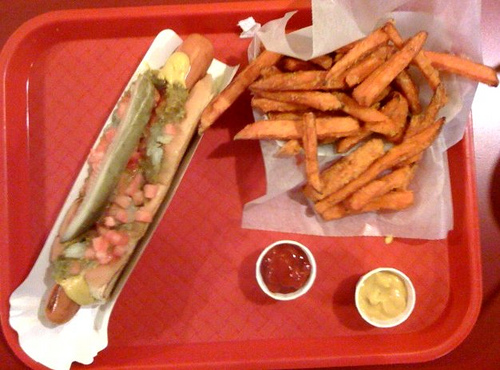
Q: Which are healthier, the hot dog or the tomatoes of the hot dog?
A: The tomatoes are healthier than the hot dog.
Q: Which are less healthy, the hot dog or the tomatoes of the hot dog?
A: The hot dog are less healthy than the tomatoes.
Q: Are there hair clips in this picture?
A: No, there are no hair clips.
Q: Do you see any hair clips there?
A: No, there are no hair clips.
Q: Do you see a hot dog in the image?
A: Yes, there is a hot dog.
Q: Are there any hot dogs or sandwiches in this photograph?
A: Yes, there is a hot dog.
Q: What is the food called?
A: The food is a hot dog.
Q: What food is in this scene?
A: The food is a hot dog.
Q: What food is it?
A: The food is a hot dog.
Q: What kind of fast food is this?
A: This is a hot dog.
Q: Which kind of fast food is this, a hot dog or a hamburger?
A: This is a hot dog.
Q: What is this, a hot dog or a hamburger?
A: This is a hot dog.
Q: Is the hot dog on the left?
A: Yes, the hot dog is on the left of the image.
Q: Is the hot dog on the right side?
A: No, the hot dog is on the left of the image.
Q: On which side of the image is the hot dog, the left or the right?
A: The hot dog is on the left of the image.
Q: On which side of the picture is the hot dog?
A: The hot dog is on the left of the image.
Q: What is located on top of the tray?
A: The hot dog is on top of the tray.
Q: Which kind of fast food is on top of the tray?
A: The food is a hot dog.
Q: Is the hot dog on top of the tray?
A: Yes, the hot dog is on top of the tray.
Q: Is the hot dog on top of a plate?
A: No, the hot dog is on top of the tray.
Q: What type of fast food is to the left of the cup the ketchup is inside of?
A: The food is a hot dog.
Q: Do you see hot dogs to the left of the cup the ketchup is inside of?
A: Yes, there is a hot dog to the left of the cup.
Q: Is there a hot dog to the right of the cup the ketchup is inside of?
A: No, the hot dog is to the left of the cup.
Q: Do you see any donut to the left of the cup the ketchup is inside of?
A: No, there is a hot dog to the left of the cup.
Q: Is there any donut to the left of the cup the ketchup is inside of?
A: No, there is a hot dog to the left of the cup.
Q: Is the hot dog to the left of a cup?
A: Yes, the hot dog is to the left of a cup.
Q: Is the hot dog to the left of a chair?
A: No, the hot dog is to the left of a cup.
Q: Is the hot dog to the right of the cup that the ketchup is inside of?
A: No, the hot dog is to the left of the cup.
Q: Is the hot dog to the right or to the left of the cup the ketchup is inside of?
A: The hot dog is to the left of the cup.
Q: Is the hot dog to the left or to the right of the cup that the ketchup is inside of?
A: The hot dog is to the left of the cup.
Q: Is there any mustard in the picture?
A: Yes, there is mustard.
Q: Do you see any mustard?
A: Yes, there is mustard.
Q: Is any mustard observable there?
A: Yes, there is mustard.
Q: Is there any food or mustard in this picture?
A: Yes, there is mustard.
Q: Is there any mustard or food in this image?
A: Yes, there is mustard.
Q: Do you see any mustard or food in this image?
A: Yes, there is mustard.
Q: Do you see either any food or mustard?
A: Yes, there is mustard.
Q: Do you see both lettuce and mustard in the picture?
A: No, there is mustard but no lettuce.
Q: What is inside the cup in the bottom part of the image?
A: The mustard is inside the cup.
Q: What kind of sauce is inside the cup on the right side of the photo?
A: The sauce is mustard.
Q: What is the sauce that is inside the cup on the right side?
A: The sauce is mustard.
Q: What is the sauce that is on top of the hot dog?
A: The sauce is mustard.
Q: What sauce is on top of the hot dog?
A: The sauce is mustard.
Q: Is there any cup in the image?
A: Yes, there is a cup.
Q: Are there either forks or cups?
A: Yes, there is a cup.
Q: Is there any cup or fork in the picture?
A: Yes, there is a cup.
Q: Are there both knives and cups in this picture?
A: No, there is a cup but no knives.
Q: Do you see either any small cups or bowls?
A: Yes, there is a small cup.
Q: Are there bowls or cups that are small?
A: Yes, the cup is small.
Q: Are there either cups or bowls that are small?
A: Yes, the cup is small.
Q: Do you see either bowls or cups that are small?
A: Yes, the cup is small.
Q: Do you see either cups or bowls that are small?
A: Yes, the cup is small.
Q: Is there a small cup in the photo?
A: Yes, there is a small cup.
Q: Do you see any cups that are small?
A: Yes, there is a cup that is small.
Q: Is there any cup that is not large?
A: Yes, there is a small cup.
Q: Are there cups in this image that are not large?
A: Yes, there is a small cup.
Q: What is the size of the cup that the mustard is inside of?
A: The cup is small.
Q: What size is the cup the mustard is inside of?
A: The cup is small.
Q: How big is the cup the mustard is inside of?
A: The cup is small.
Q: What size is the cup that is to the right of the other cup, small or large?
A: The cup is small.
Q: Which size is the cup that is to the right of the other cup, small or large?
A: The cup is small.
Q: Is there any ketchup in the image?
A: Yes, there is ketchup.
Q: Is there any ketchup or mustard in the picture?
A: Yes, there is ketchup.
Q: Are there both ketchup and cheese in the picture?
A: No, there is ketchup but no cheese.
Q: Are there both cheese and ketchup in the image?
A: No, there is ketchup but no cheese.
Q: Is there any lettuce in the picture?
A: No, there is no lettuce.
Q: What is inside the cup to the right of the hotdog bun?
A: The ketchup is inside the cup.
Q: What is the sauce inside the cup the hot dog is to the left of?
A: The sauce is ketchup.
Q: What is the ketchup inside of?
A: The ketchup is inside the cup.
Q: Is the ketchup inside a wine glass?
A: No, the ketchup is inside a cup.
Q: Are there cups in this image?
A: Yes, there is a cup.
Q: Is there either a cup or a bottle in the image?
A: Yes, there is a cup.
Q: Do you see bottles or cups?
A: Yes, there is a cup.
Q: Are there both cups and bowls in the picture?
A: No, there is a cup but no bowls.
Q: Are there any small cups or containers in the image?
A: Yes, there is a small cup.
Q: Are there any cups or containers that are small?
A: Yes, the cup is small.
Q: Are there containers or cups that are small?
A: Yes, the cup is small.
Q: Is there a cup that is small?
A: Yes, there is a cup that is small.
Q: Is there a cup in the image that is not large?
A: Yes, there is a small cup.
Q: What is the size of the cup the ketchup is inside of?
A: The cup is small.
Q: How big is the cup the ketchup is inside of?
A: The cup is small.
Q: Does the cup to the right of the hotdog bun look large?
A: No, the cup is small.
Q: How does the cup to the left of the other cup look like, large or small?
A: The cup is small.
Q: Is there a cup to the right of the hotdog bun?
A: Yes, there is a cup to the right of the hotdog bun.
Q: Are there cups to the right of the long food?
A: Yes, there is a cup to the right of the hotdog bun.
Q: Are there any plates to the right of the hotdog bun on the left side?
A: No, there is a cup to the right of the hotdog bun.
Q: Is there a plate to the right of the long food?
A: No, there is a cup to the right of the hotdog bun.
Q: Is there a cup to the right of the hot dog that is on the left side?
A: Yes, there is a cup to the right of the hot dog.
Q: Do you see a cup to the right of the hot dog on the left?
A: Yes, there is a cup to the right of the hot dog.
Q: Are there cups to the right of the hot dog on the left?
A: Yes, there is a cup to the right of the hot dog.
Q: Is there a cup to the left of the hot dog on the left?
A: No, the cup is to the right of the hot dog.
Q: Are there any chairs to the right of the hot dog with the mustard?
A: No, there is a cup to the right of the hot dog.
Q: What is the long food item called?
A: The food item is a hotdog bun.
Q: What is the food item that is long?
A: The food item is a hotdog bun.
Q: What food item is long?
A: The food item is a hotdog bun.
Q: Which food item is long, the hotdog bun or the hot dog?
A: The hotdog bun is long.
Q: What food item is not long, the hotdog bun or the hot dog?
A: The hot dog is not long.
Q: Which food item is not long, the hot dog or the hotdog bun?
A: The hot dog is not long.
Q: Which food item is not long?
A: The food item is a hot dog.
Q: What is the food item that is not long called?
A: The food item is a hot dog.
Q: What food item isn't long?
A: The food item is a hot dog.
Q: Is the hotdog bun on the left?
A: Yes, the hotdog bun is on the left of the image.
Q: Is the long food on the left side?
A: Yes, the hotdog bun is on the left of the image.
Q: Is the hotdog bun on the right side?
A: No, the hotdog bun is on the left of the image.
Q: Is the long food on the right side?
A: No, the hotdog bun is on the left of the image.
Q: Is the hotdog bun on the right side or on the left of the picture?
A: The hotdog bun is on the left of the image.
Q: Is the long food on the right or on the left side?
A: The hotdog bun is on the left of the image.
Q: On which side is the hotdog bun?
A: The hotdog bun is on the left of the image.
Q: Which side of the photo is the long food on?
A: The hotdog bun is on the left of the image.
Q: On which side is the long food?
A: The hotdog bun is on the left of the image.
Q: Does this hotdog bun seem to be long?
A: Yes, the hotdog bun is long.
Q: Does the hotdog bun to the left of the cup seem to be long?
A: Yes, the hotdog bun is long.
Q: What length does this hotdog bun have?
A: The hotdog bun has long length.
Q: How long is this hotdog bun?
A: The hotdog bun is long.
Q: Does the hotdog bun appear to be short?
A: No, the hotdog bun is long.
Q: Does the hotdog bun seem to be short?
A: No, the hotdog bun is long.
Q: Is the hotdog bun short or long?
A: The hotdog bun is long.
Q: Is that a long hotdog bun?
A: Yes, that is a long hotdog bun.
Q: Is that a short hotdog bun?
A: No, that is a long hotdog bun.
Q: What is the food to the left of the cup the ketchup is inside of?
A: The food is a hotdog bun.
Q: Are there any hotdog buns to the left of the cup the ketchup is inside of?
A: Yes, there is a hotdog bun to the left of the cup.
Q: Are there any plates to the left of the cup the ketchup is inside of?
A: No, there is a hotdog bun to the left of the cup.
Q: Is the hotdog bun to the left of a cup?
A: Yes, the hotdog bun is to the left of a cup.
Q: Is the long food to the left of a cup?
A: Yes, the hotdog bun is to the left of a cup.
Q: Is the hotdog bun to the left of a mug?
A: No, the hotdog bun is to the left of a cup.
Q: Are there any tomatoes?
A: Yes, there are tomatoes.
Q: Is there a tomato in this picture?
A: Yes, there are tomatoes.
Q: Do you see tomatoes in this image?
A: Yes, there are tomatoes.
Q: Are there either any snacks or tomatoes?
A: Yes, there are tomatoes.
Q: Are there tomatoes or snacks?
A: Yes, there are tomatoes.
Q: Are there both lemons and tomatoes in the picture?
A: No, there are tomatoes but no lemons.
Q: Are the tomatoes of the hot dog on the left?
A: Yes, the tomatoes are on the left of the image.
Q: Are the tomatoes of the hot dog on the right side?
A: No, the tomatoes are on the left of the image.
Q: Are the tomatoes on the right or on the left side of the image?
A: The tomatoes are on the left of the image.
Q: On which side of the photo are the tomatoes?
A: The tomatoes are on the left of the image.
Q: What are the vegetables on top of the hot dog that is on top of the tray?
A: The vegetables are tomatoes.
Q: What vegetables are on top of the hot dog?
A: The vegetables are tomatoes.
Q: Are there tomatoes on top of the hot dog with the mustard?
A: Yes, there are tomatoes on top of the hot dog.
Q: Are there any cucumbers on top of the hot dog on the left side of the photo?
A: No, there are tomatoes on top of the hot dog.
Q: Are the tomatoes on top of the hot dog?
A: Yes, the tomatoes are on top of the hot dog.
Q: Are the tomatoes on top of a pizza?
A: No, the tomatoes are on top of the hot dog.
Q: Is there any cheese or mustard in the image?
A: Yes, there is mustard.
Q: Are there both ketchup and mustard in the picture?
A: Yes, there are both mustard and ketchup.